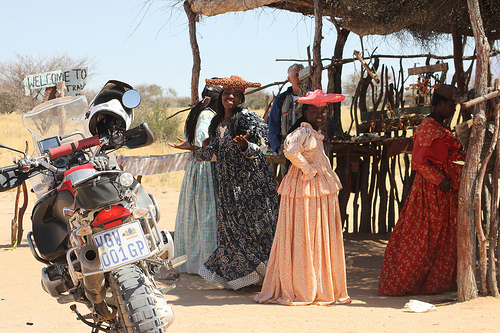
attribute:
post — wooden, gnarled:
[453, 2, 490, 299]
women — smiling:
[129, 57, 361, 331]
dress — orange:
[228, 73, 386, 310]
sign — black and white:
[20, 60, 88, 102]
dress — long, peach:
[380, 122, 465, 302]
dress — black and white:
[190, 109, 277, 289]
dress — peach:
[252, 123, 349, 305]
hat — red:
[283, 77, 370, 124]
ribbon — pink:
[196, 73, 216, 111]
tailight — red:
[91, 205, 131, 228]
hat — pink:
[292, 87, 342, 107]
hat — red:
[294, 86, 341, 106]